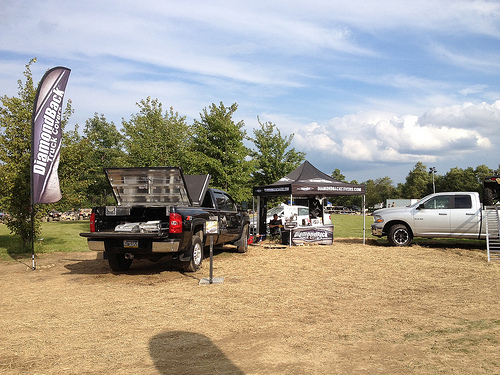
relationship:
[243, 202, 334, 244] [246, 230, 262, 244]
car has front wheel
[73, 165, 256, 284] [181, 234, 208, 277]
truck has back wheel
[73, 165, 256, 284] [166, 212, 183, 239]
truck has back light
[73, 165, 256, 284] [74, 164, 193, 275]
truck has back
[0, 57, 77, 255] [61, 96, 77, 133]
tree has branch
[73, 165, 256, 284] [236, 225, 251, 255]
truck has front wheel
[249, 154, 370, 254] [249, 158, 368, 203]
tent has upper part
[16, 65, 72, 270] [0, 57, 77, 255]
banner near tree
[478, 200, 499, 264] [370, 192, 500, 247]
ladder near car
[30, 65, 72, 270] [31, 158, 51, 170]
banner has letter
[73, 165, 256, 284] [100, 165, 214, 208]
truck has cover